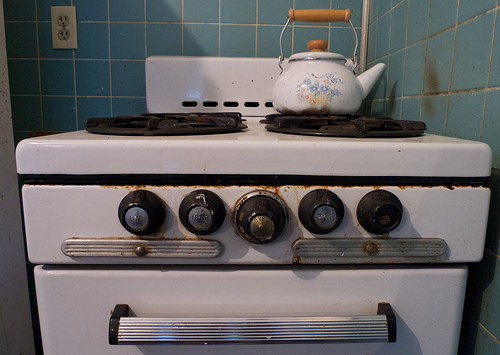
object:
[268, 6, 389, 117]
kettle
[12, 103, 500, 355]
stove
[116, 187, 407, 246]
knobs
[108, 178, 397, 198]
rust stains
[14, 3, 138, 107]
wall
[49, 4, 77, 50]
outlet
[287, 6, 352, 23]
handle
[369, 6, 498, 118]
tiles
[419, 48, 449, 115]
burn stain